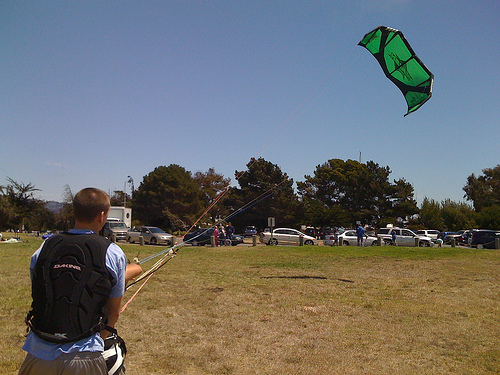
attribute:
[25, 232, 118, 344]
chest protector — black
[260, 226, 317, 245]
car — silver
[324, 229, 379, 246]
car — silver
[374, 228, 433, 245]
car — silver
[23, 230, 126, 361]
shirt — blue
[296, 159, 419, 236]
tree — large, green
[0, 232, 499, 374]
grass — green, dead, brown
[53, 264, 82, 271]
lettering — white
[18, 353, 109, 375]
shorts — grey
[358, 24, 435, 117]
kite — green, black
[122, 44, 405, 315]
strings — blue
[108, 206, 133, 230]
truck — silver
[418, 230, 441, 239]
car — white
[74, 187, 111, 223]
blonde hair — brown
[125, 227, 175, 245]
car — tan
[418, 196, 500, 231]
trees — short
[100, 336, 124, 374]
bookbag — black